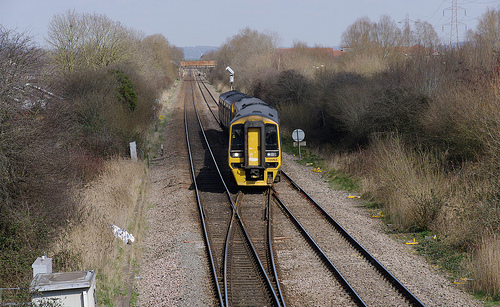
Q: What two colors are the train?
A: Yellow and black.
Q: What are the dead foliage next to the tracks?
A: Trees.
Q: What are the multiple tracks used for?
A: Train.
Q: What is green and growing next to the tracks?
A: Grass.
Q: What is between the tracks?
A: Gravel.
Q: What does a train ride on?
A: Tracks.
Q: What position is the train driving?
A: Forward.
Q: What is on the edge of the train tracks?
A: Shrubs.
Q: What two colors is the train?
A: Yellow and black.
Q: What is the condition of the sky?
A: Blue and clear.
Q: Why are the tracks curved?
A: Switching track area.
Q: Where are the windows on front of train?
A: Top sides.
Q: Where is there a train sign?
A: To the right of train.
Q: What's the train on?
A: Tracks.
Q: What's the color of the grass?
A: Brown.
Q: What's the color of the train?
A: Yellow.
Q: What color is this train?
A: Black and yellow.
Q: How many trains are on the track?
A: One.